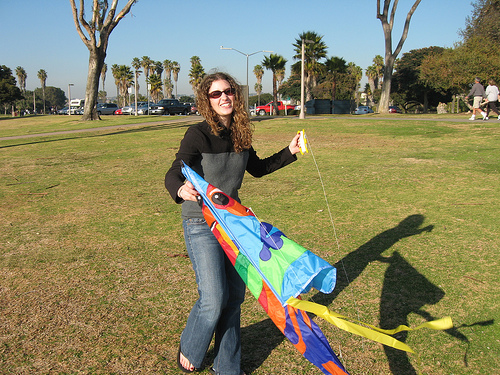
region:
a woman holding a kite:
[140, 53, 437, 348]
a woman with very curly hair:
[188, 58, 263, 164]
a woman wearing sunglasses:
[188, 54, 268, 152]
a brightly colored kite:
[171, 154, 384, 356]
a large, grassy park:
[5, 5, 497, 352]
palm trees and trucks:
[111, 45, 186, 112]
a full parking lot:
[55, 87, 197, 119]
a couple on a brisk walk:
[465, 71, 496, 124]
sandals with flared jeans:
[162, 295, 209, 370]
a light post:
[211, 37, 282, 69]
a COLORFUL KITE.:
[171, 159, 366, 374]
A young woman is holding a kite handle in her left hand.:
[160, 70, 325, 206]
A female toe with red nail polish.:
[185, 362, 195, 368]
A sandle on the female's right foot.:
[162, 330, 198, 373]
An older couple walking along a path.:
[468, 59, 499, 124]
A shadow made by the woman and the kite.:
[304, 187, 464, 349]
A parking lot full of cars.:
[57, 82, 297, 129]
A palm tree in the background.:
[263, 44, 289, 116]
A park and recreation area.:
[3, 97, 493, 357]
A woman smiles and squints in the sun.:
[211, 81, 235, 115]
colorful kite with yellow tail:
[172, 148, 442, 372]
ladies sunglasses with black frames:
[197, 84, 237, 101]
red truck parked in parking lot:
[244, 96, 299, 131]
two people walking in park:
[430, 71, 498, 125]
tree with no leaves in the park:
[52, 0, 160, 124]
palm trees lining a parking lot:
[105, 48, 186, 125]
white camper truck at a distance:
[59, 92, 95, 124]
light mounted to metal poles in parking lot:
[215, 36, 283, 114]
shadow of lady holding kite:
[277, 171, 480, 373]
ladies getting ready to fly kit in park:
[134, 46, 444, 373]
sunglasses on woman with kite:
[204, 85, 240, 98]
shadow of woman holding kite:
[344, 208, 451, 313]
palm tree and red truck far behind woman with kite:
[260, 50, 286, 115]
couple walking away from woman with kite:
[464, 72, 499, 122]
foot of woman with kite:
[172, 336, 201, 373]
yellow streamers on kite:
[303, 296, 457, 353]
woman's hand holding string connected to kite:
[286, 125, 322, 162]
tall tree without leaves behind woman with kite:
[370, 1, 417, 111]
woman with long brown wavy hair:
[194, 68, 251, 145]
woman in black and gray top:
[174, 70, 304, 187]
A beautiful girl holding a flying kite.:
[162, 65, 454, 374]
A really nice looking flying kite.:
[177, 159, 454, 374]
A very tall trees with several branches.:
[70, 2, 134, 122]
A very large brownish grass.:
[2, 111, 497, 373]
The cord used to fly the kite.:
[294, 126, 363, 329]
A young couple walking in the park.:
[460, 76, 498, 121]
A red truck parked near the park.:
[253, 96, 295, 119]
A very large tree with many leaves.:
[416, 0, 498, 110]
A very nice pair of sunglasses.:
[208, 84, 235, 101]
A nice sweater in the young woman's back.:
[162, 119, 299, 204]